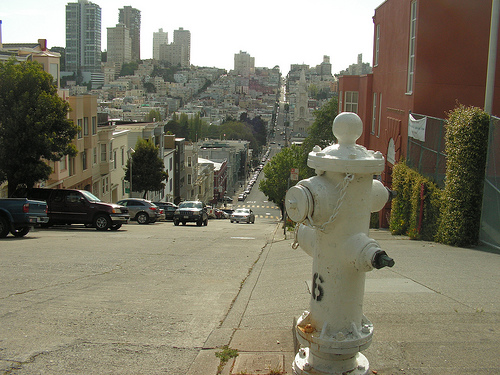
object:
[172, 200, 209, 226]
car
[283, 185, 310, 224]
cap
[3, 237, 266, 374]
cracks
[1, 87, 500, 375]
road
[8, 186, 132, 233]
car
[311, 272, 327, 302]
6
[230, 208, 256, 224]
car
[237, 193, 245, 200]
car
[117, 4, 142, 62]
building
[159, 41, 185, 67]
building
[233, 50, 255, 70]
building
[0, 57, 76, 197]
tree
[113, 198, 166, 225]
car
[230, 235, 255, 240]
manhole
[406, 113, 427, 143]
banner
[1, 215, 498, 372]
hill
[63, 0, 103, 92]
building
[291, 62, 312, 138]
building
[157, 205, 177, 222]
car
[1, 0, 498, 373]
city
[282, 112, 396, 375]
hydrant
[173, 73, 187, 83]
buildings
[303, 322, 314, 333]
bolt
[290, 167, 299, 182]
traffic sign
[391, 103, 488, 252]
hedge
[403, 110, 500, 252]
fence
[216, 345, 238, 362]
grass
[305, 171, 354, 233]
chain